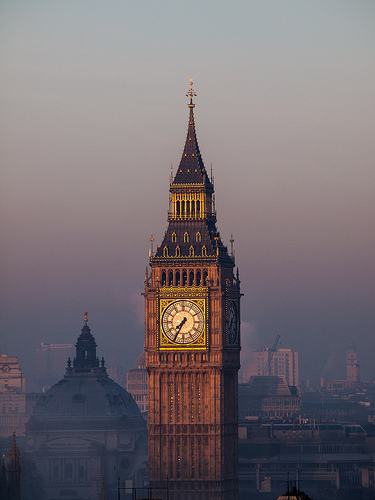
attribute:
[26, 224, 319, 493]
city — hazy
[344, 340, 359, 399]
building — tall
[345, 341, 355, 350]
dome — green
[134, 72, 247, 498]
architecture — historical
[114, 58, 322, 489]
tower — brown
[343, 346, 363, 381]
fog building — large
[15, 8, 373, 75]
sky — gray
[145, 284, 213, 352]
clock — square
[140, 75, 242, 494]
tower — brown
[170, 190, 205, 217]
accents — gold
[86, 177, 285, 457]
tower — brown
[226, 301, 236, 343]
clock — narrow